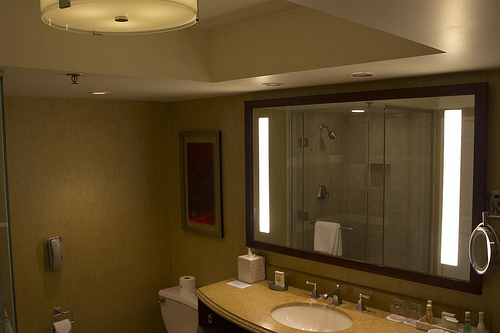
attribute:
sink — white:
[262, 295, 369, 331]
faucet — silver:
[302, 272, 373, 315]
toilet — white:
[156, 283, 199, 328]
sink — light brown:
[245, 272, 369, 331]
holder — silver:
[47, 301, 77, 326]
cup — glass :
[386, 297, 406, 324]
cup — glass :
[406, 302, 422, 330]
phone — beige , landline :
[33, 229, 77, 284]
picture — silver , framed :
[169, 124, 229, 244]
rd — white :
[209, 273, 264, 295]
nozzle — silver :
[316, 116, 340, 143]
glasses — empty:
[388, 293, 426, 329]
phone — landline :
[47, 236, 65, 275]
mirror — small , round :
[467, 222, 498, 275]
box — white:
[238, 255, 268, 283]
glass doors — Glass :
[281, 110, 445, 282]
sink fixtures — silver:
[273, 269, 374, 331]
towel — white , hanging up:
[310, 220, 345, 258]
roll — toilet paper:
[230, 250, 270, 281]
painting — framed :
[172, 123, 229, 240]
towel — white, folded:
[318, 211, 346, 266]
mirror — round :
[250, 106, 469, 281]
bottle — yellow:
[423, 299, 435, 322]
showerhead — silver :
[316, 119, 339, 146]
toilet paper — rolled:
[178, 271, 198, 291]